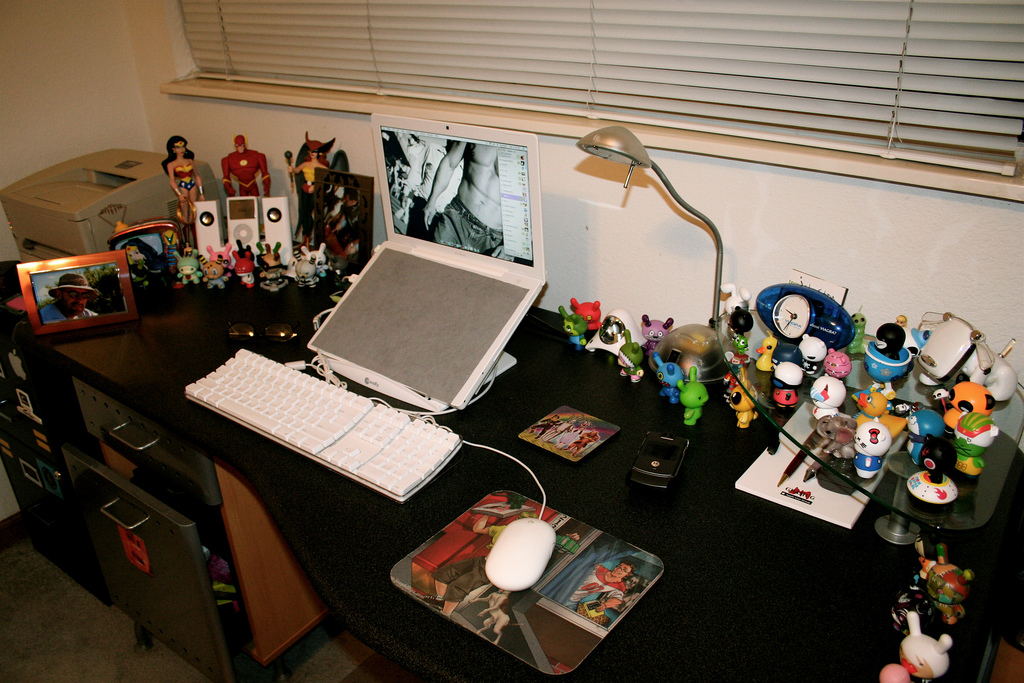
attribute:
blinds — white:
[174, 1, 1022, 179]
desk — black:
[3, 234, 1022, 678]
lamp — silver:
[572, 124, 728, 387]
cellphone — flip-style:
[624, 423, 695, 493]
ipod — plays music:
[226, 194, 262, 255]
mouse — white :
[391, 482, 666, 672]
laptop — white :
[313, 109, 548, 414]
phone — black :
[631, 421, 690, 491]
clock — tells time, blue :
[777, 291, 809, 337]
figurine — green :
[651, 352, 683, 403]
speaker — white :
[259, 196, 292, 263]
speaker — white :
[195, 197, 221, 259]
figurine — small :
[907, 433, 961, 504]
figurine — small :
[954, 409, 1000, 474]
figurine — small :
[906, 405, 946, 467]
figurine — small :
[825, 343, 851, 376]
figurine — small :
[798, 332, 828, 378]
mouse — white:
[486, 516, 556, 589]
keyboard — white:
[186, 346, 465, 503]